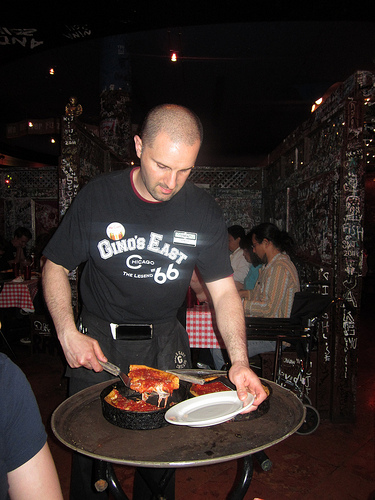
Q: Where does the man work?
A: Gino's East restaurant.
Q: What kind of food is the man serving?
A: Pizza.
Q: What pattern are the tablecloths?
A: Gingham.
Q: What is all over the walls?
A: Writing or graffiti.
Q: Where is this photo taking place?
A: In a restaurant.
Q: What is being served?
A: Pizza.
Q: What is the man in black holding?
A: A plate.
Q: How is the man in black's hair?
A: Buzz cut.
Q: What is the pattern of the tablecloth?
A: Plaid.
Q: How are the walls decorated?
A: With writing.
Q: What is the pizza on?
A: Large brown tray.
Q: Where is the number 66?
A: Man's shirt.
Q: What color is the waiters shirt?
A: Black.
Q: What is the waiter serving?
A: Pizza.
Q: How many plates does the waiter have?
A: One.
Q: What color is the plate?
A: White.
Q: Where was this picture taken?
A: Restaurant.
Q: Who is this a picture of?
A: Waiter.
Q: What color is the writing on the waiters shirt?
A: White.